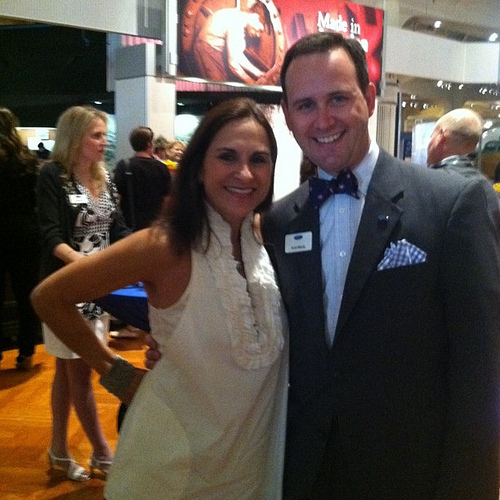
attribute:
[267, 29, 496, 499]
man — smiling, bald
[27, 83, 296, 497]
woman — smiling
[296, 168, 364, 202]
bowtie — dark blue, blue, spotted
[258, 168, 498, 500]
suit — gray, grey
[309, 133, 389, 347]
shirt — blue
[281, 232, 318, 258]
nametag — small, white, blue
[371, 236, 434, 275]
pocket square — blue, checkered, white, gingham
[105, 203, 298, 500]
white top — long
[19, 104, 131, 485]
woman — blonde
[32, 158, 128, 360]
dress — black, white, ruffled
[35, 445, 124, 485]
sandles — white, high heel, strappy, high heeled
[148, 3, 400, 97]
sign — red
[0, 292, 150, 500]
floor — woodpaneled, brown, hardwood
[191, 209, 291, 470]
front — ruffled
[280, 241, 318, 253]
writing — black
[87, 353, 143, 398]
bracelet — thick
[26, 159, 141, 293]
cardigan — black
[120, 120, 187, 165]
three people — talking